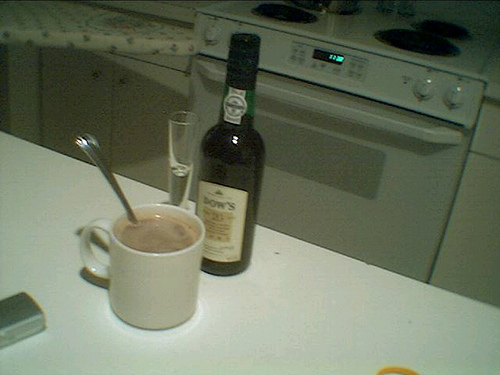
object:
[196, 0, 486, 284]
stove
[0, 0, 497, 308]
cabinet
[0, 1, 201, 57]
ironing board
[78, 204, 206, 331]
coffee